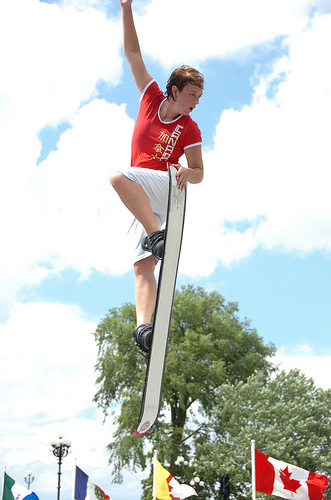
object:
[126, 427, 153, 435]
red trim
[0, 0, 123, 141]
clouds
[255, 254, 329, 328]
sky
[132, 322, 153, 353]
foot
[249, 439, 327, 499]
canadian flag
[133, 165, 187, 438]
board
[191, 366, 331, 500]
tree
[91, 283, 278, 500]
tree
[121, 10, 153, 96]
arm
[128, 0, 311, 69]
cloud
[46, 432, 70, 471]
lights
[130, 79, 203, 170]
shirt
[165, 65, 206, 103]
hair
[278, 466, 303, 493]
maple leaf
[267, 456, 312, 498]
flag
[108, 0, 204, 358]
boy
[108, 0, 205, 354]
girl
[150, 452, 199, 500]
country flag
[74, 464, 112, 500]
country flag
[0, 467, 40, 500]
country flag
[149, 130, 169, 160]
word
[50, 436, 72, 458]
globe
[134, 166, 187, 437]
ski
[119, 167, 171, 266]
shorts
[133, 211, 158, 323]
legs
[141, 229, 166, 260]
foot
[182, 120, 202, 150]
sleeve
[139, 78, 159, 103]
sleeve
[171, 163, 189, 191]
hand